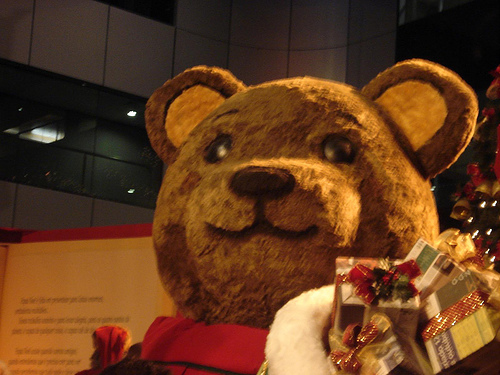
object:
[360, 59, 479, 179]
bears ear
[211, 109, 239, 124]
eye brow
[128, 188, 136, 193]
light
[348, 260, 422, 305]
bow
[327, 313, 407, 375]
boxes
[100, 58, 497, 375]
bear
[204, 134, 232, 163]
eye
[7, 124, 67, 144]
light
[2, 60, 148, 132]
ceiling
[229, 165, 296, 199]
nose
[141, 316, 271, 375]
red collar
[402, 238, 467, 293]
gift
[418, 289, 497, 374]
gift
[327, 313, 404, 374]
gift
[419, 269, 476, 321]
gift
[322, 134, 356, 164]
eye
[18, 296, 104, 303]
writing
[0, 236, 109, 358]
wall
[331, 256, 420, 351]
boxes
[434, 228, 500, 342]
gifts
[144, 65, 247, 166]
ear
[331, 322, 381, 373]
bow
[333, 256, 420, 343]
gift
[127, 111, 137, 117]
lamp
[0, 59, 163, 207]
windows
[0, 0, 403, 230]
building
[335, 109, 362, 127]
eyebrow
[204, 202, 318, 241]
mouth